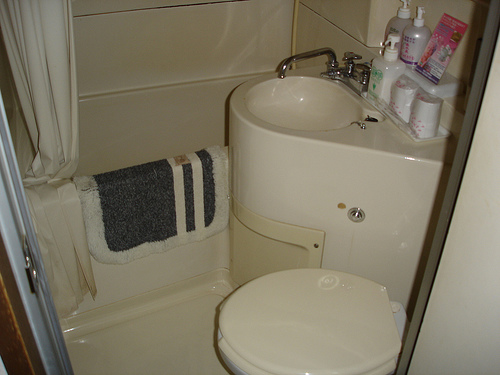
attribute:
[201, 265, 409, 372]
toilet — here, white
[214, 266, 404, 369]
lid — white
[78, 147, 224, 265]
rug — blue, white, gray, black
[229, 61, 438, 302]
sink — small, fiberglass, round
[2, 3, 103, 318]
curtain — cream, vinyl, white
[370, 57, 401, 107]
soap — white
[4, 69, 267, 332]
bathtub — empty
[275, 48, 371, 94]
faucet — metal, steel, silver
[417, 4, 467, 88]
paper — pink, colorful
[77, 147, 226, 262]
mat — here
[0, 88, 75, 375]
door — sliding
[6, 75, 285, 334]
tub — miniature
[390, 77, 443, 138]
cups — wrapped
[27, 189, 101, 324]
towel — white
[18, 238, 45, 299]
hinge — silver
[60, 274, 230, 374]
baseboard — cream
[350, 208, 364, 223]
button — silver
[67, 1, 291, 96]
wall — tiled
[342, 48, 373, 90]
handles — silver